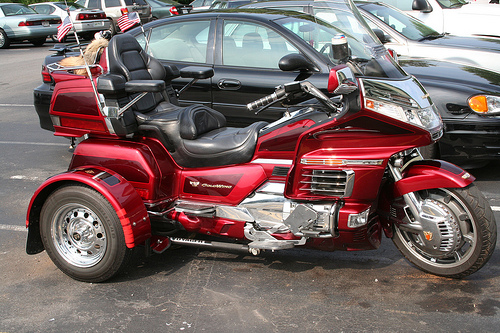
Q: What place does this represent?
A: It represents the street.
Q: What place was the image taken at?
A: It was taken at the street.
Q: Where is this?
A: This is at the street.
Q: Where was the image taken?
A: It was taken at the street.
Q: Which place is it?
A: It is a street.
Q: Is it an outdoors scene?
A: Yes, it is outdoors.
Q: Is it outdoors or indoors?
A: It is outdoors.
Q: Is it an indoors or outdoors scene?
A: It is outdoors.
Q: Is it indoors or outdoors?
A: It is outdoors.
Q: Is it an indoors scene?
A: No, it is outdoors.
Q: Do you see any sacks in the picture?
A: No, there are no sacks.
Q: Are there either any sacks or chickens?
A: No, there are no sacks or chickens.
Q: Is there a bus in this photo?
A: No, there are no buses.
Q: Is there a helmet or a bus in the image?
A: No, there are no buses or helmets.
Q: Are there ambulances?
A: No, there are no ambulances.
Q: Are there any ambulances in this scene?
A: No, there are no ambulances.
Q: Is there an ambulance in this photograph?
A: No, there are no ambulances.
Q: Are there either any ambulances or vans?
A: No, there are no ambulances or vans.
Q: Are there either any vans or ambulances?
A: No, there are no ambulances or vans.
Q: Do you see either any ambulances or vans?
A: No, there are no ambulances or vans.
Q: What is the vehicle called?
A: The vehicle is a car.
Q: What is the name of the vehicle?
A: The vehicle is a car.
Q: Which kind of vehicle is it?
A: The vehicle is a car.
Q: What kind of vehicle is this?
A: This is a car.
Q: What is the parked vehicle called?
A: The vehicle is a car.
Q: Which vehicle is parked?
A: The vehicle is a car.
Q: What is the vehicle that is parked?
A: The vehicle is a car.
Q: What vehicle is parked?
A: The vehicle is a car.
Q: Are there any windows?
A: Yes, there is a window.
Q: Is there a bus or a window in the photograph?
A: Yes, there is a window.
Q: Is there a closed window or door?
A: Yes, there is a closed window.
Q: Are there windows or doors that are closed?
A: Yes, the window is closed.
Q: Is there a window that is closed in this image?
A: Yes, there is a closed window.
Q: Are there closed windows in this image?
A: Yes, there is a closed window.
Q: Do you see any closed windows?
A: Yes, there is a closed window.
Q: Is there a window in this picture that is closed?
A: Yes, there is a closed window.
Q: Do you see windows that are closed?
A: Yes, there is a window that is closed.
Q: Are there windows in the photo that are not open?
A: Yes, there is an closed window.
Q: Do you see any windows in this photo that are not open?
A: Yes, there is an closed window.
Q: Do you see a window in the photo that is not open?
A: Yes, there is an closed window.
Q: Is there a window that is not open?
A: Yes, there is an closed window.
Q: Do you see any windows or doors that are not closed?
A: No, there is a window but it is closed.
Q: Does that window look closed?
A: Yes, the window is closed.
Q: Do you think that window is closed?
A: Yes, the window is closed.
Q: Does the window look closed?
A: Yes, the window is closed.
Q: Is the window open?
A: No, the window is closed.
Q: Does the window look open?
A: No, the window is closed.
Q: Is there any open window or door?
A: No, there is a window but it is closed.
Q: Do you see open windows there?
A: No, there is a window but it is closed.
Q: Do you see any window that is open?
A: No, there is a window but it is closed.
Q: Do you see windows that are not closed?
A: No, there is a window but it is closed.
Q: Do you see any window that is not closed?
A: No, there is a window but it is closed.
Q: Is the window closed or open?
A: The window is closed.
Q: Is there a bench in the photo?
A: No, there are no benches.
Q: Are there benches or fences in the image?
A: No, there are no benches or fences.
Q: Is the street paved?
A: Yes, the street is paved.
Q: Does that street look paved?
A: Yes, the street is paved.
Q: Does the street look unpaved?
A: No, the street is paved.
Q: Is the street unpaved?
A: No, the street is paved.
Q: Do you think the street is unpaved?
A: No, the street is paved.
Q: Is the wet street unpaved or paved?
A: The street is paved.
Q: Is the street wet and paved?
A: Yes, the street is wet and paved.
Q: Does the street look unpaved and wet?
A: No, the street is wet but paved.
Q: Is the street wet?
A: Yes, the street is wet.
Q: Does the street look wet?
A: Yes, the street is wet.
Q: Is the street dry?
A: No, the street is wet.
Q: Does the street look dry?
A: No, the street is wet.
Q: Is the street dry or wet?
A: The street is wet.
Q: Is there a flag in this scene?
A: Yes, there is a flag.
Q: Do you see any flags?
A: Yes, there is a flag.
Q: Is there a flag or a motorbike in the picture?
A: Yes, there is a flag.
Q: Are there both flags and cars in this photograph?
A: Yes, there are both a flag and a car.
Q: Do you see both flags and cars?
A: Yes, there are both a flag and a car.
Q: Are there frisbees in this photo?
A: No, there are no frisbees.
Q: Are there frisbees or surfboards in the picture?
A: No, there are no frisbees or surfboards.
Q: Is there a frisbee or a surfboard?
A: No, there are no frisbees or surfboards.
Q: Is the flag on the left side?
A: Yes, the flag is on the left of the image.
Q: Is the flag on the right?
A: No, the flag is on the left of the image.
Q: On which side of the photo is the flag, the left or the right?
A: The flag is on the left of the image.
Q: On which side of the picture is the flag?
A: The flag is on the left of the image.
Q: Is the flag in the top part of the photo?
A: Yes, the flag is in the top of the image.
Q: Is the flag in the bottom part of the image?
A: No, the flag is in the top of the image.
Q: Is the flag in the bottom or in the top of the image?
A: The flag is in the top of the image.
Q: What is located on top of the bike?
A: The flag is on top of the bike.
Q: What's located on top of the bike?
A: The flag is on top of the bike.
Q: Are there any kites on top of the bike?
A: No, there is a flag on top of the bike.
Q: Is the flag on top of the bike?
A: Yes, the flag is on top of the bike.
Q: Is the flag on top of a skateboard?
A: No, the flag is on top of the bike.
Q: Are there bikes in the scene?
A: Yes, there is a bike.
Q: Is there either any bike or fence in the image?
A: Yes, there is a bike.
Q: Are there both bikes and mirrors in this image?
A: Yes, there are both a bike and a mirror.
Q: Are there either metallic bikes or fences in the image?
A: Yes, there is a metal bike.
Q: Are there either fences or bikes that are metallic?
A: Yes, the bike is metallic.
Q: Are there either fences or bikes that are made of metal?
A: Yes, the bike is made of metal.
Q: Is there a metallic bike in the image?
A: Yes, there is a metal bike.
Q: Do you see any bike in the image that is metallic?
A: Yes, there is a bike that is metallic.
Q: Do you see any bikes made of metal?
A: Yes, there is a bike that is made of metal.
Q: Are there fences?
A: No, there are no fences.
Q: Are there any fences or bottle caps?
A: No, there are no fences or bottle caps.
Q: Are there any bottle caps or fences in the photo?
A: No, there are no fences or bottle caps.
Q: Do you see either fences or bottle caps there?
A: No, there are no fences or bottle caps.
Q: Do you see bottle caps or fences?
A: No, there are no fences or bottle caps.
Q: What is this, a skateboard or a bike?
A: This is a bike.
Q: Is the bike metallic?
A: Yes, the bike is metallic.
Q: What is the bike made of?
A: The bike is made of metal.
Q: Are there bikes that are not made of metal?
A: No, there is a bike but it is made of metal.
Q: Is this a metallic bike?
A: Yes, this is a metallic bike.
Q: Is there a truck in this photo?
A: No, there are no trucks.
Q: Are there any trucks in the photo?
A: No, there are no trucks.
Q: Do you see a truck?
A: No, there are no trucks.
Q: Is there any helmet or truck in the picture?
A: No, there are no trucks or helmets.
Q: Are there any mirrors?
A: Yes, there is a mirror.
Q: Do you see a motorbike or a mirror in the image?
A: Yes, there is a mirror.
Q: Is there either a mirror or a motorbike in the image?
A: Yes, there is a mirror.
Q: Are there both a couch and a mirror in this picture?
A: No, there is a mirror but no couches.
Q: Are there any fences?
A: No, there are no fences.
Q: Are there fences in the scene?
A: No, there are no fences.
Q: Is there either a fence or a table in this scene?
A: No, there are no fences or tables.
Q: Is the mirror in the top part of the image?
A: Yes, the mirror is in the top of the image.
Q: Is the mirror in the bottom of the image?
A: No, the mirror is in the top of the image.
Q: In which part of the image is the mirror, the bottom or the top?
A: The mirror is in the top of the image.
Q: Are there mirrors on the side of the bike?
A: Yes, there is a mirror on the side of the bike.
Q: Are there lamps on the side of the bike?
A: No, there is a mirror on the side of the bike.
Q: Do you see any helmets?
A: No, there are no helmets.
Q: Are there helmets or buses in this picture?
A: No, there are no helmets or buses.